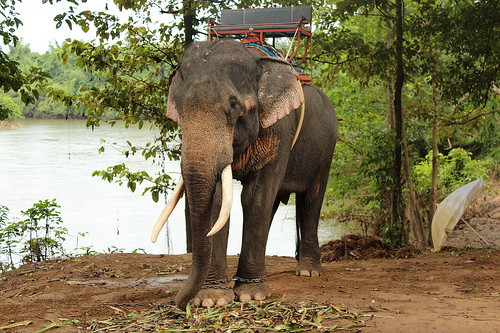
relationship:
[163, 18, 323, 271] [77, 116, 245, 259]
elephant by river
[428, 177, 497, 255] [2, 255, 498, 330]
umbrella sitting on ground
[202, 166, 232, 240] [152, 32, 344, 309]
tusk on elephant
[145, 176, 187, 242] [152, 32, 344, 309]
tusk on elephant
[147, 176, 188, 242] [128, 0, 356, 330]
tusk on elephant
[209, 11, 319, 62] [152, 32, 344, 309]
chair on top of elephant